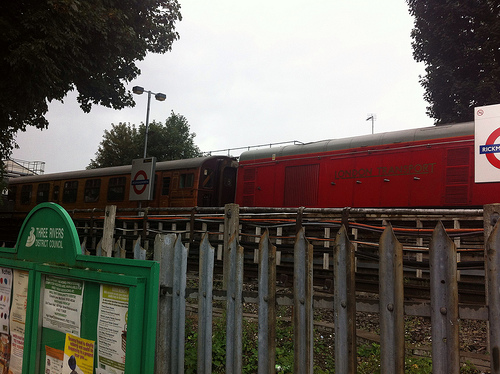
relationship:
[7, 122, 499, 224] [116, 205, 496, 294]
train on bridge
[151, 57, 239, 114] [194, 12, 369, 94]
cloud in sky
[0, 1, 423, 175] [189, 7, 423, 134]
cloud in sky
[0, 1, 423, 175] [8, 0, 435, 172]
cloud in sky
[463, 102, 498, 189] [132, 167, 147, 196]
sign with circle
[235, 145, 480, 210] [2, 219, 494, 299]
car train on tracks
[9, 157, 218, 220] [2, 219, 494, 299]
car train on tracks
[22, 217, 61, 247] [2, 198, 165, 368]
lettering on frame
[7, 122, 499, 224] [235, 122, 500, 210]
train with car train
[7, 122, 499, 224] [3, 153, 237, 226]
train with car train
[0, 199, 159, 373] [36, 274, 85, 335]
board with notices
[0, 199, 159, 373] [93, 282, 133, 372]
board with notices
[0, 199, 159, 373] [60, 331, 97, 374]
board with flyer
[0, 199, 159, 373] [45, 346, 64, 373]
board with notices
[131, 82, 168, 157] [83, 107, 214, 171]
street lamp in front of tree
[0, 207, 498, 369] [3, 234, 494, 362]
picket fence near tracks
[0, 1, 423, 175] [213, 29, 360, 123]
cloud in sky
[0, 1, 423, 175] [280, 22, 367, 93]
cloud in sky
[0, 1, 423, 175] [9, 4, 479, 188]
cloud in sky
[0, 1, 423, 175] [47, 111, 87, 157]
cloud in sky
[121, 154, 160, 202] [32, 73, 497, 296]
sign on train